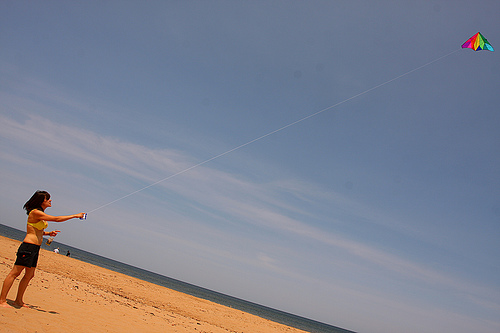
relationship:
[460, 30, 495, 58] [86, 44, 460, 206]
kite has string attached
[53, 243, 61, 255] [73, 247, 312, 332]
man on shoreline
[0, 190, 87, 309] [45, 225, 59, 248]
lady holding bottle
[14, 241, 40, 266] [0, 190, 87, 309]
shorts on woman